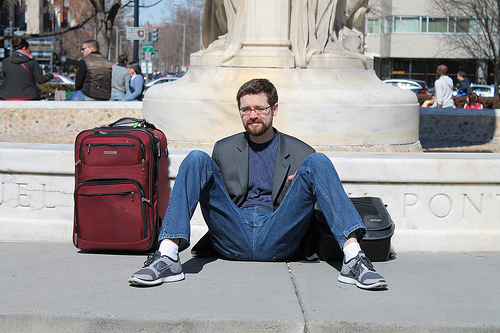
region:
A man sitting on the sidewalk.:
[135, 71, 385, 322]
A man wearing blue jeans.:
[150, 66, 371, 317]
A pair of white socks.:
[145, 226, 365, 258]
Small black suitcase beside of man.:
[320, 185, 395, 261]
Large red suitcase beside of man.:
[65, 111, 170, 256]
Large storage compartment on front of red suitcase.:
[70, 171, 150, 241]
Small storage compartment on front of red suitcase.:
[70, 130, 145, 170]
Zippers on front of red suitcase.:
[72, 130, 153, 245]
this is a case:
[65, 108, 170, 250]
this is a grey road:
[406, 242, 454, 310]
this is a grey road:
[50, 275, 117, 329]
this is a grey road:
[411, 210, 463, 303]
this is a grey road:
[245, 272, 297, 321]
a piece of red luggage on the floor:
[71, 113, 165, 249]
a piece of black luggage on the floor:
[310, 192, 395, 267]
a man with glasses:
[236, 105, 276, 114]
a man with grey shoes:
[127, 252, 189, 287]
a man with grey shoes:
[335, 255, 385, 291]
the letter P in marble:
[400, 188, 418, 221]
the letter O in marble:
[423, 189, 452, 223]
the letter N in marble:
[460, 192, 487, 219]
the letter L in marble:
[40, 181, 57, 211]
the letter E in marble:
[13, 179, 30, 209]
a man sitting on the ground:
[135, 75, 381, 291]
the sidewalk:
[0, 237, 495, 323]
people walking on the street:
[426, 66, 463, 97]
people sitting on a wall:
[0, 31, 110, 93]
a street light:
[146, 20, 157, 40]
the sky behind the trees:
[130, 5, 181, 25]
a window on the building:
[390, 12, 425, 32]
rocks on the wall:
[3, 108, 84, 140]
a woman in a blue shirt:
[123, 60, 145, 100]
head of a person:
[225, 61, 302, 136]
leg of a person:
[151, 182, 219, 239]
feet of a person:
[105, 252, 220, 307]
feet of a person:
[320, 260, 425, 313]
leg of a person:
[316, 158, 390, 262]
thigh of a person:
[188, 182, 248, 270]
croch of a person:
[243, 204, 302, 261]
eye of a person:
[232, 100, 256, 118]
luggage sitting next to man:
[72, 115, 168, 254]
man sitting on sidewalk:
[128, 78, 387, 290]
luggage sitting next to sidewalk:
[309, 196, 394, 260]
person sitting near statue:
[65, 38, 110, 100]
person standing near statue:
[109, 50, 131, 102]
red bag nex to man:
[73, 117, 167, 250]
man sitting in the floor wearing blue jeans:
[127, 76, 389, 291]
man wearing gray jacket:
[206, 128, 312, 208]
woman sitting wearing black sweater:
[0, 36, 46, 99]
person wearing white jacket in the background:
[427, 59, 456, 106]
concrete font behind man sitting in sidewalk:
[0, 0, 497, 257]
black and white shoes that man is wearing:
[129, 246, 385, 286]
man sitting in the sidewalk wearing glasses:
[127, 74, 400, 286]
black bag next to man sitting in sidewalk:
[311, 191, 391, 261]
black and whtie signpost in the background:
[124, 25, 148, 42]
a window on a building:
[361, 16, 381, 34]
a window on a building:
[382, 19, 394, 32]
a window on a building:
[399, 17, 419, 30]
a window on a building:
[418, 12, 430, 31]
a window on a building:
[428, 19, 446, 34]